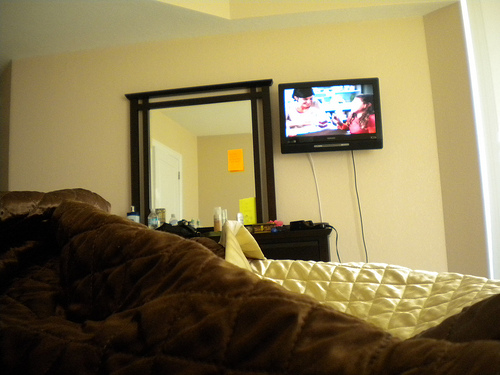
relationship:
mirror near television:
[122, 79, 273, 236] [277, 77, 383, 155]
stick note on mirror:
[235, 193, 257, 227] [122, 79, 273, 236]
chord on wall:
[350, 150, 369, 265] [17, 20, 449, 267]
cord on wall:
[303, 151, 328, 228] [281, 3, 473, 276]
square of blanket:
[446, 287, 478, 312] [221, 250, 498, 342]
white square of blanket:
[350, 279, 378, 301] [244, 261, 499, 345]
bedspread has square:
[0, 186, 499, 374] [367, 298, 399, 314]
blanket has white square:
[217, 220, 500, 341] [408, 270, 436, 284]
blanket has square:
[217, 220, 500, 341] [379, 269, 410, 285]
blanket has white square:
[217, 220, 500, 341] [332, 265, 356, 280]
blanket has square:
[217, 220, 500, 341] [323, 280, 355, 302]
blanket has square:
[217, 220, 500, 341] [367, 297, 399, 314]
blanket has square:
[263, 256, 465, 356] [423, 291, 452, 306]